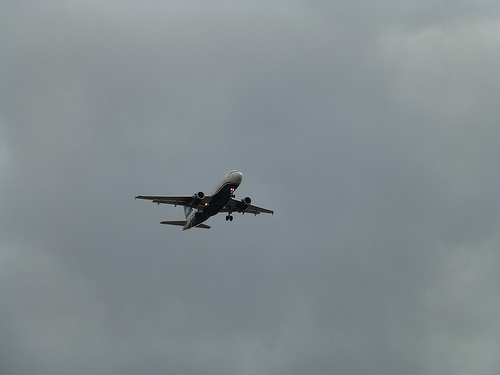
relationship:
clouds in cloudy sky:
[0, 0, 499, 375] [0, 1, 499, 374]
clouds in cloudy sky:
[167, 25, 357, 140] [0, 1, 499, 374]